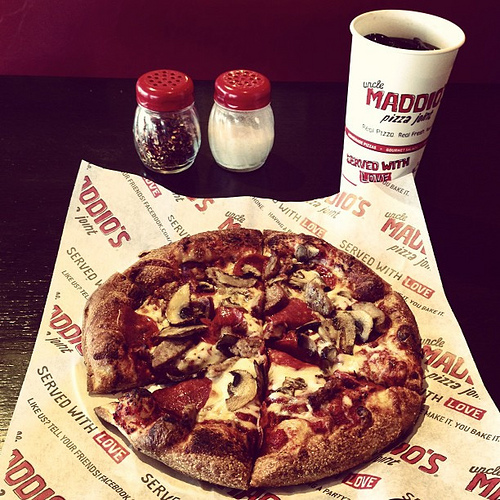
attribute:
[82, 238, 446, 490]
pizza — topped, sliced, cheesy, crusty, round, brown, white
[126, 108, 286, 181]
glass — capped, filled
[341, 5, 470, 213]
cup — white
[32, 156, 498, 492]
paper — white